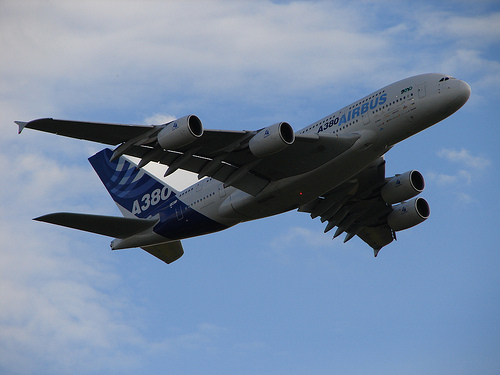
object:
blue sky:
[1, 0, 497, 372]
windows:
[393, 101, 396, 105]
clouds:
[120, 11, 238, 55]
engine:
[249, 120, 295, 157]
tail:
[30, 147, 187, 265]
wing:
[11, 113, 363, 197]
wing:
[297, 155, 440, 258]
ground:
[425, 132, 499, 198]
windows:
[332, 115, 335, 118]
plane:
[8, 71, 475, 259]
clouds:
[178, 23, 343, 74]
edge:
[31, 210, 159, 239]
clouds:
[145, 22, 340, 89]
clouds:
[139, 36, 259, 76]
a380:
[132, 186, 173, 216]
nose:
[436, 74, 471, 104]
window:
[399, 97, 403, 101]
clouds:
[439, 146, 486, 181]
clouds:
[12, 12, 34, 81]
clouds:
[23, 294, 121, 345]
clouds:
[49, 13, 178, 45]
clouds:
[300, 38, 355, 77]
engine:
[378, 166, 426, 205]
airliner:
[12, 71, 472, 266]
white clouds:
[21, 19, 146, 85]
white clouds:
[215, 8, 390, 83]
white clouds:
[5, 233, 119, 283]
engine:
[156, 113, 205, 151]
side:
[12, 66, 347, 268]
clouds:
[1, 12, 400, 66]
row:
[361, 89, 415, 117]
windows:
[439, 76, 450, 82]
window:
[410, 93, 413, 97]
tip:
[436, 74, 476, 112]